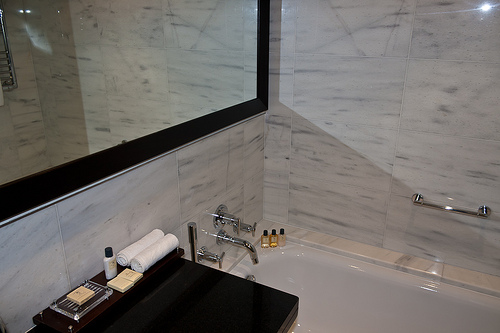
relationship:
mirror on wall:
[0, 5, 299, 213] [3, 10, 315, 309]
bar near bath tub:
[412, 190, 490, 220] [256, 224, 486, 331]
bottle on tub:
[276, 227, 290, 249] [277, 249, 439, 331]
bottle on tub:
[267, 227, 277, 246] [277, 249, 439, 331]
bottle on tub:
[260, 227, 269, 249] [277, 249, 439, 331]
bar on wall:
[412, 190, 490, 220] [229, 20, 499, 306]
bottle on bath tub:
[278, 228, 286, 247] [226, 241, 500, 333]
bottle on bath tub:
[269, 229, 278, 247] [226, 241, 500, 333]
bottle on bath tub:
[261, 230, 269, 249] [226, 241, 500, 333]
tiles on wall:
[265, 0, 499, 277] [3, 3, 479, 315]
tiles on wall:
[172, 114, 269, 263] [3, 3, 479, 315]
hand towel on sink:
[130, 232, 180, 273] [93, 269, 310, 324]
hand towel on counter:
[115, 228, 164, 267] [29, 246, 300, 331]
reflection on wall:
[417, 4, 498, 17] [262, 4, 499, 298]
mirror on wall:
[0, 0, 258, 186] [3, 2, 265, 330]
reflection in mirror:
[0, 0, 258, 185] [0, 5, 299, 213]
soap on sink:
[63, 254, 130, 331] [0, 257, 292, 331]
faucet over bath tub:
[192, 205, 259, 267] [226, 241, 500, 333]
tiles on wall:
[289, 11, 478, 190] [262, 4, 499, 298]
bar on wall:
[412, 190, 494, 220] [262, 4, 499, 298]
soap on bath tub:
[260, 227, 285, 248] [226, 241, 500, 333]